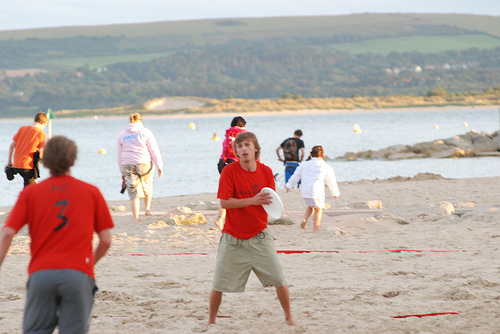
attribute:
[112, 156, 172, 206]
shorts — brown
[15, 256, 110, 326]
shorts — gray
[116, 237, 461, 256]
line — red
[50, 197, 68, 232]
number — black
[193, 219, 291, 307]
shorts — khaki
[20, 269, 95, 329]
shorts — gray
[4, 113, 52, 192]
man — orange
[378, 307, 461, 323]
line — red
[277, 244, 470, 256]
line — red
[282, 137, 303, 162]
shirt — black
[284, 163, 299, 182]
shorts — blue